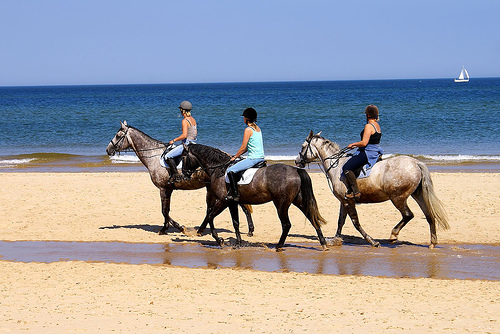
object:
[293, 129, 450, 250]
horse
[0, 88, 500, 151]
ocean water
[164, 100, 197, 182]
woman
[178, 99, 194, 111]
helmet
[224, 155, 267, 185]
saddle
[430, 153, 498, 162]
waves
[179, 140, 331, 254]
horse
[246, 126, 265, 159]
blue top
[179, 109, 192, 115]
blonde hair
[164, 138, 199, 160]
jeans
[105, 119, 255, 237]
horse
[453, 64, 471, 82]
sailboat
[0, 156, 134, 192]
sand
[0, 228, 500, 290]
wet patch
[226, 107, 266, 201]
woman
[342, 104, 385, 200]
woman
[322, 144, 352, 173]
reigns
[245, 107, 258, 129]
hair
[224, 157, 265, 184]
jeans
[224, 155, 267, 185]
padding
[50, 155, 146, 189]
beach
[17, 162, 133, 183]
shore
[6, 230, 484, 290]
sand